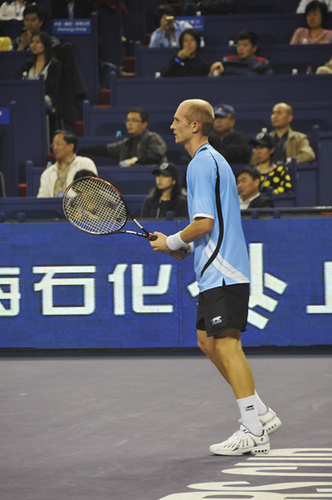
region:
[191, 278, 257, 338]
tennis player's black shorts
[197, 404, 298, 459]
tennis player's white sneakers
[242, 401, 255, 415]
logo on a white sock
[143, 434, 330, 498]
white writing on a tennis court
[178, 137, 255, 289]
blue shirt with white and black stripes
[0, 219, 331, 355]
blue wall with white writing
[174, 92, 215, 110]
tennis player's bald head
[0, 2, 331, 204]
stand full of people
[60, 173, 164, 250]
tennis racket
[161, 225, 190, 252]
white sweatband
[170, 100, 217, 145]
The man's hair is blonde.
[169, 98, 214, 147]
The man's hair is short.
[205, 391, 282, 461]
The man's shoes are white and black.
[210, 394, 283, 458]
The man's socks are black and white.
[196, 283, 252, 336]
The man is wearing shorts.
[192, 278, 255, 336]
The man is wearing black shorts.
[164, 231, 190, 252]
The man is wearing a white wrist band.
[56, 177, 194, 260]
The man is holding a tennis racket.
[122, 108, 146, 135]
The man is wearing glasses.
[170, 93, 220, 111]
man's bald head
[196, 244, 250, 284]
white stripes on shirt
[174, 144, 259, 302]
long blue jersey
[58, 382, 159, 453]
gray color on the ground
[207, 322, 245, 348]
brown shorts under black shorts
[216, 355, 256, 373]
tan color on man's leg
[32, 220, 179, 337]
blue wall on the court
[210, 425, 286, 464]
white and gray sneakers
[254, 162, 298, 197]
black and yellow polka dot shirt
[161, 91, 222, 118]
tennis player's bald head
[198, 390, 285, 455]
tennis player's white shoes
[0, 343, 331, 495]
grey colored tennis court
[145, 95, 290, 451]
tennis player on the court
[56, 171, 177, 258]
tennis racket in the man's hand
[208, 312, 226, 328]
logo on a pair of black shorts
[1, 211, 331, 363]
short blue wall near a tennis court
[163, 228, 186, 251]
white wrist band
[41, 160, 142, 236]
Black,white,and orange racket in man's hand.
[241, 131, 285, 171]
Black,white,and orange racket in man's hand.